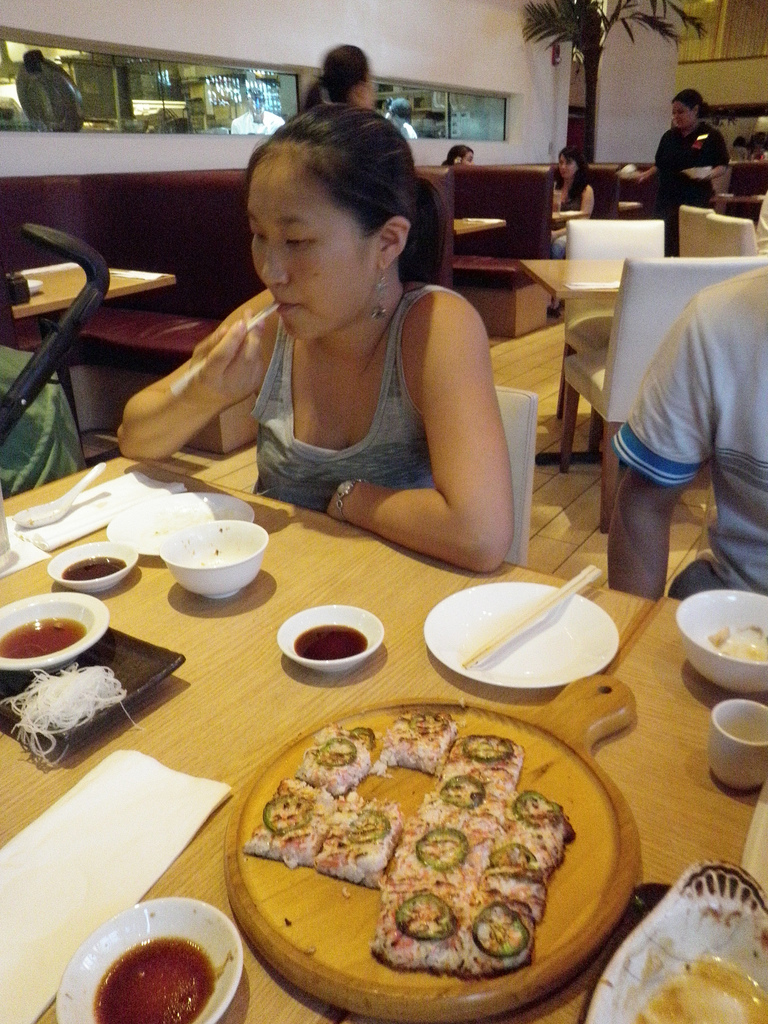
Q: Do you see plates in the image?
A: Yes, there is a plate.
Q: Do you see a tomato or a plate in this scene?
A: Yes, there is a plate.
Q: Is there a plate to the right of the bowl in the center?
A: Yes, there is a plate to the right of the bowl.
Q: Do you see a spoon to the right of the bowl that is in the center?
A: No, there is a plate to the right of the bowl.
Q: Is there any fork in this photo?
A: No, there are no forks.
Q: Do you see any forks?
A: No, there are no forks.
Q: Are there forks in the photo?
A: No, there are no forks.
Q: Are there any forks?
A: No, there are no forks.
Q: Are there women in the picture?
A: Yes, there is a woman.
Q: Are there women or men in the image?
A: Yes, there is a woman.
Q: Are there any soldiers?
A: No, there are no soldiers.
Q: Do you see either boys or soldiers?
A: No, there are no soldiers or boys.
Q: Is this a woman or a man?
A: This is a woman.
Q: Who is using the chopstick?
A: The woman is using the chopstick.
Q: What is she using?
A: The woman is using a chopstick.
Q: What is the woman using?
A: The woman is using a chopstick.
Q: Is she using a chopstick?
A: Yes, the woman is using a chopstick.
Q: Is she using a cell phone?
A: No, the woman is using a chopstick.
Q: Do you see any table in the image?
A: Yes, there is a table.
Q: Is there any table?
A: Yes, there is a table.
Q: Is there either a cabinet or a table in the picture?
A: Yes, there is a table.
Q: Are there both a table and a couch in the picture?
A: No, there is a table but no couches.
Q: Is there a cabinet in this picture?
A: No, there are no cabinets.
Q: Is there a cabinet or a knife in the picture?
A: No, there are no cabinets or knives.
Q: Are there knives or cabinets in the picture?
A: No, there are no cabinets or knives.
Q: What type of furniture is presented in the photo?
A: The furniture is a table.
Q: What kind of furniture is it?
A: The piece of furniture is a table.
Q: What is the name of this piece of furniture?
A: This is a table.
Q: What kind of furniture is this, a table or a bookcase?
A: This is a table.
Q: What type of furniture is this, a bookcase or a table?
A: This is a table.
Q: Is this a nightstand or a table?
A: This is a table.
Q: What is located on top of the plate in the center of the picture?
A: The chopstick is on top of the plate.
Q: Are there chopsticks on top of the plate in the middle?
A: Yes, there is a chopstick on top of the plate.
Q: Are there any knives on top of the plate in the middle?
A: No, there is a chopstick on top of the plate.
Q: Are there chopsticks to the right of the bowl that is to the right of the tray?
A: Yes, there is a chopstick to the right of the bowl.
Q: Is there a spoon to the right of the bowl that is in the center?
A: No, there is a chopstick to the right of the bowl.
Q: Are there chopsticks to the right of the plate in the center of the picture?
A: Yes, there is a chopstick to the right of the plate.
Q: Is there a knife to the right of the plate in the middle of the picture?
A: No, there is a chopstick to the right of the plate.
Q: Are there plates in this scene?
A: Yes, there is a plate.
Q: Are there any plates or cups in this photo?
A: Yes, there is a plate.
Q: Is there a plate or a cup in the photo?
A: Yes, there is a plate.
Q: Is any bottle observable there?
A: No, there are no bottles.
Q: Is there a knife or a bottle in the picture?
A: No, there are no bottles or knives.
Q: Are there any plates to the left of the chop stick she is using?
A: Yes, there is a plate to the left of the chopstick.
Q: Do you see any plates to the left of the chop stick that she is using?
A: Yes, there is a plate to the left of the chopstick.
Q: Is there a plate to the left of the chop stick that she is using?
A: Yes, there is a plate to the left of the chopstick.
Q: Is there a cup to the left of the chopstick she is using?
A: No, there is a plate to the left of the chopstick.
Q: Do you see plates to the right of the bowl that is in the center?
A: Yes, there is a plate to the right of the bowl.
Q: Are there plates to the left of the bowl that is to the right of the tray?
A: No, the plate is to the right of the bowl.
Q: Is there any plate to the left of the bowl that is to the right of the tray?
A: No, the plate is to the right of the bowl.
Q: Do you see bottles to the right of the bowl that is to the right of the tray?
A: No, there is a plate to the right of the bowl.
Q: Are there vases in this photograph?
A: No, there are no vases.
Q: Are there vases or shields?
A: No, there are no vases or shields.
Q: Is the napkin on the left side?
A: Yes, the napkin is on the left of the image.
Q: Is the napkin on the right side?
A: No, the napkin is on the left of the image.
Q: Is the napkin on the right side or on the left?
A: The napkin is on the left of the image.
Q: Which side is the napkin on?
A: The napkin is on the left of the image.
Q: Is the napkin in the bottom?
A: Yes, the napkin is in the bottom of the image.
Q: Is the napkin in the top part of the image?
A: No, the napkin is in the bottom of the image.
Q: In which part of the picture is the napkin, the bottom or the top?
A: The napkin is in the bottom of the image.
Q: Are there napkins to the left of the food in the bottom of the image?
A: Yes, there is a napkin to the left of the food.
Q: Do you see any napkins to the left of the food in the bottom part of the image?
A: Yes, there is a napkin to the left of the food.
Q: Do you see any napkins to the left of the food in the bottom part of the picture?
A: Yes, there is a napkin to the left of the food.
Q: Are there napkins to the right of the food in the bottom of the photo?
A: No, the napkin is to the left of the food.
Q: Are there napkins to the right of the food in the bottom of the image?
A: No, the napkin is to the left of the food.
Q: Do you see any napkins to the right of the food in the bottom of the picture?
A: No, the napkin is to the left of the food.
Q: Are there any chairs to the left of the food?
A: No, there is a napkin to the left of the food.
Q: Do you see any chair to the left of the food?
A: No, there is a napkin to the left of the food.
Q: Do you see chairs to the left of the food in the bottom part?
A: No, there is a napkin to the left of the food.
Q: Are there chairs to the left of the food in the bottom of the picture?
A: No, there is a napkin to the left of the food.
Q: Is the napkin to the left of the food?
A: Yes, the napkin is to the left of the food.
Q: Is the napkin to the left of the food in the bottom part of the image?
A: Yes, the napkin is to the left of the food.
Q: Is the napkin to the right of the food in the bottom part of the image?
A: No, the napkin is to the left of the food.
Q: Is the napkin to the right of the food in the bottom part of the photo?
A: No, the napkin is to the left of the food.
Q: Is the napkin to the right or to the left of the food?
A: The napkin is to the left of the food.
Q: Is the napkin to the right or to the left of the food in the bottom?
A: The napkin is to the left of the food.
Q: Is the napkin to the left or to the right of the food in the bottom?
A: The napkin is to the left of the food.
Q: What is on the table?
A: The napkin is on the table.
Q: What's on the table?
A: The napkin is on the table.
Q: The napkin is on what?
A: The napkin is on the table.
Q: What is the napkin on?
A: The napkin is on the table.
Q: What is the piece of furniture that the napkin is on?
A: The piece of furniture is a table.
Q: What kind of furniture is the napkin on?
A: The napkin is on the table.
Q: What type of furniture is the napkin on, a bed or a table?
A: The napkin is on a table.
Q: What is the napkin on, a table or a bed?
A: The napkin is on a table.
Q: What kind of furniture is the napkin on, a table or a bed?
A: The napkin is on a table.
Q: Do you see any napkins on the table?
A: Yes, there is a napkin on the table.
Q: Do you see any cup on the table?
A: No, there is a napkin on the table.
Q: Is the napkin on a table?
A: Yes, the napkin is on a table.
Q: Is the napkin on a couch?
A: No, the napkin is on a table.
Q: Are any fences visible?
A: No, there are no fences.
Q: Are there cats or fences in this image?
A: No, there are no fences or cats.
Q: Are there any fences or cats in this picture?
A: No, there are no fences or cats.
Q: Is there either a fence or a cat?
A: No, there are no fences or cats.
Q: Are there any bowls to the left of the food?
A: Yes, there is a bowl to the left of the food.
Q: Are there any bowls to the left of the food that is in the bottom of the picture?
A: Yes, there is a bowl to the left of the food.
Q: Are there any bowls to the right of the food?
A: No, the bowl is to the left of the food.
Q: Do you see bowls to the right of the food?
A: No, the bowl is to the left of the food.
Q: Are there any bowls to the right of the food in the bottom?
A: No, the bowl is to the left of the food.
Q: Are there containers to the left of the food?
A: No, there is a bowl to the left of the food.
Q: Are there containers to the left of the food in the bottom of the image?
A: No, there is a bowl to the left of the food.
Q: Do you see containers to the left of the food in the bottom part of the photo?
A: No, there is a bowl to the left of the food.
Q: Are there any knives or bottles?
A: No, there are no bottles or knives.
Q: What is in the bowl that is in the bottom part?
A: The sauce is in the bowl.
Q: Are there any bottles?
A: No, there are no bottles.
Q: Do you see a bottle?
A: No, there are no bottles.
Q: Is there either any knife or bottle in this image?
A: No, there are no bottles or knives.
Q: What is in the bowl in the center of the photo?
A: The sauce is in the bowl.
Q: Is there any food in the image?
A: Yes, there is food.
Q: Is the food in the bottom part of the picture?
A: Yes, the food is in the bottom of the image.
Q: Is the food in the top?
A: No, the food is in the bottom of the image.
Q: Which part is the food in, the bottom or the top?
A: The food is in the bottom of the image.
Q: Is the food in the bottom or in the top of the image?
A: The food is in the bottom of the image.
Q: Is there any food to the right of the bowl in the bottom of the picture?
A: Yes, there is food to the right of the bowl.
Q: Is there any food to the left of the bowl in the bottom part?
A: No, the food is to the right of the bowl.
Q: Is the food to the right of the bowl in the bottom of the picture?
A: Yes, the food is to the right of the bowl.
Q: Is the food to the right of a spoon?
A: No, the food is to the right of the bowl.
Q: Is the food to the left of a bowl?
A: No, the food is to the right of a bowl.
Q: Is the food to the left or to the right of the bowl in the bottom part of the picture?
A: The food is to the right of the bowl.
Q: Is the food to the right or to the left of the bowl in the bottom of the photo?
A: The food is to the right of the bowl.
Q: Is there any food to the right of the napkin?
A: Yes, there is food to the right of the napkin.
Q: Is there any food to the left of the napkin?
A: No, the food is to the right of the napkin.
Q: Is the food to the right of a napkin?
A: Yes, the food is to the right of a napkin.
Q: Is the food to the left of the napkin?
A: No, the food is to the right of the napkin.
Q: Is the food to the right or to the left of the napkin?
A: The food is to the right of the napkin.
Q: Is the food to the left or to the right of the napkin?
A: The food is to the right of the napkin.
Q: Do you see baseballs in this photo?
A: No, there are no baseballs.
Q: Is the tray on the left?
A: Yes, the tray is on the left of the image.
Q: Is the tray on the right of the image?
A: No, the tray is on the left of the image.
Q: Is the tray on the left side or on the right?
A: The tray is on the left of the image.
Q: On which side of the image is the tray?
A: The tray is on the left of the image.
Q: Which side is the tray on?
A: The tray is on the left of the image.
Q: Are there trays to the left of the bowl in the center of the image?
A: Yes, there is a tray to the left of the bowl.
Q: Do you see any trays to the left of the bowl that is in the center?
A: Yes, there is a tray to the left of the bowl.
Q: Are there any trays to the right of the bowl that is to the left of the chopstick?
A: No, the tray is to the left of the bowl.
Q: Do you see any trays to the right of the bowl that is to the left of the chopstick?
A: No, the tray is to the left of the bowl.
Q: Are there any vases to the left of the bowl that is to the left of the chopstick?
A: No, there is a tray to the left of the bowl.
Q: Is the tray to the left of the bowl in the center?
A: Yes, the tray is to the left of the bowl.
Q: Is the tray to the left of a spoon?
A: No, the tray is to the left of the bowl.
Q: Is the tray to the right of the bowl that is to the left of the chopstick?
A: No, the tray is to the left of the bowl.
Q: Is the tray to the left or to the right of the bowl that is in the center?
A: The tray is to the left of the bowl.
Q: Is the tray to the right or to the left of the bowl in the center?
A: The tray is to the left of the bowl.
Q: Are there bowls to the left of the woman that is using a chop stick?
A: Yes, there is a bowl to the left of the woman.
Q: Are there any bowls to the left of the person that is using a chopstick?
A: Yes, there is a bowl to the left of the woman.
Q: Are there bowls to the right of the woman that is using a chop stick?
A: No, the bowl is to the left of the woman.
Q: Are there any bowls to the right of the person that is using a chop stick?
A: No, the bowl is to the left of the woman.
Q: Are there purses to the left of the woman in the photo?
A: No, there is a bowl to the left of the woman.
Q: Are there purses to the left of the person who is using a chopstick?
A: No, there is a bowl to the left of the woman.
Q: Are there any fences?
A: No, there are no fences.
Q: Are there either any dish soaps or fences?
A: No, there are no fences or dish soaps.